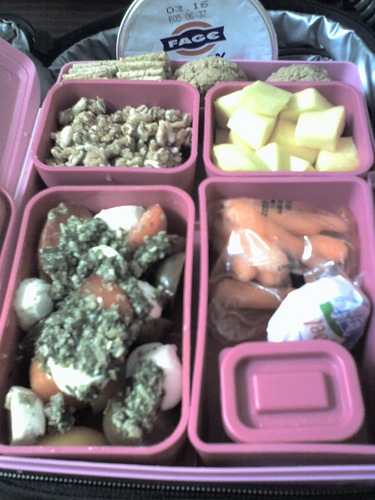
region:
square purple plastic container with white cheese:
[203, 68, 374, 176]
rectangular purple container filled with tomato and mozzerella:
[5, 177, 197, 457]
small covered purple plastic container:
[221, 340, 361, 443]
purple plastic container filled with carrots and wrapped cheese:
[185, 173, 371, 462]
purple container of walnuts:
[25, 77, 207, 183]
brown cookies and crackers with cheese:
[61, 0, 338, 79]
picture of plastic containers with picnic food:
[0, 0, 373, 490]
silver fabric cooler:
[49, 3, 374, 88]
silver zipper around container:
[2, 469, 370, 495]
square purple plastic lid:
[220, 332, 362, 441]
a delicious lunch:
[43, 22, 373, 475]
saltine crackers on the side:
[77, 53, 178, 86]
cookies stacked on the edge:
[178, 59, 332, 82]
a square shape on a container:
[252, 374, 323, 419]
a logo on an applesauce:
[159, 23, 244, 48]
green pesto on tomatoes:
[58, 313, 115, 363]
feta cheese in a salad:
[12, 390, 43, 440]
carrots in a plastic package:
[237, 201, 338, 252]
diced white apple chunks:
[239, 97, 338, 151]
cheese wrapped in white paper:
[290, 293, 359, 334]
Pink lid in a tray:
[226, 345, 356, 434]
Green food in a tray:
[29, 302, 172, 423]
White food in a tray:
[1, 383, 77, 449]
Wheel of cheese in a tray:
[274, 272, 373, 363]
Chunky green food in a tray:
[62, 98, 200, 167]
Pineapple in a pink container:
[217, 94, 368, 174]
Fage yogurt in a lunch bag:
[123, 1, 333, 54]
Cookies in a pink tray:
[173, 57, 353, 85]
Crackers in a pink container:
[66, 55, 200, 97]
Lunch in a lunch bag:
[36, 79, 358, 414]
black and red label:
[164, 18, 231, 53]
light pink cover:
[227, 343, 359, 440]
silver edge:
[288, 10, 360, 45]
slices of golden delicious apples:
[240, 89, 323, 153]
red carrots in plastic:
[234, 202, 343, 264]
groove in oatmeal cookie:
[190, 73, 208, 81]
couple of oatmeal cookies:
[176, 53, 346, 91]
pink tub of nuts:
[42, 82, 211, 179]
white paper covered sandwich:
[251, 266, 373, 373]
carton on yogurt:
[123, 1, 296, 74]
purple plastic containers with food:
[0, 72, 374, 463]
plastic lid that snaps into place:
[212, 335, 367, 442]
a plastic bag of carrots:
[210, 196, 352, 281]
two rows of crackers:
[57, 48, 175, 84]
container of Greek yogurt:
[112, 0, 280, 59]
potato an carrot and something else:
[23, 204, 172, 412]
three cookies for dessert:
[174, 58, 342, 83]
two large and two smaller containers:
[0, 76, 372, 459]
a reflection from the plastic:
[213, 226, 280, 274]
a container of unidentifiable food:
[38, 83, 194, 171]